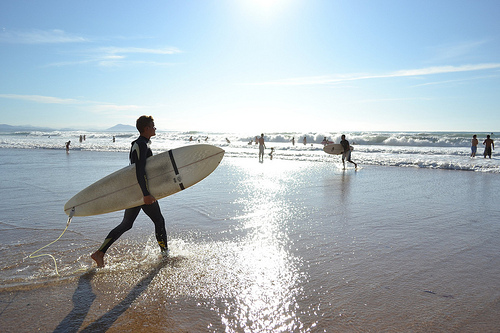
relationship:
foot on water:
[90, 252, 105, 267] [4, 132, 498, 330]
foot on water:
[162, 247, 178, 262] [4, 132, 498, 330]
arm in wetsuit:
[134, 153, 156, 207] [115, 130, 169, 267]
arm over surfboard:
[134, 153, 156, 207] [27, 145, 262, 220]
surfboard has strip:
[65, 144, 230, 231] [168, 149, 181, 192]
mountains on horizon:
[0, 117, 136, 134] [0, 104, 490, 132]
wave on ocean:
[222, 153, 498, 173] [2, 127, 498, 326]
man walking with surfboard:
[77, 117, 181, 269] [65, 144, 230, 231]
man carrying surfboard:
[77, 117, 181, 269] [65, 144, 230, 231]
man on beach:
[77, 117, 181, 269] [3, 128, 498, 331]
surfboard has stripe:
[65, 144, 230, 231] [167, 151, 184, 191]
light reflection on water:
[206, 142, 343, 331] [4, 132, 498, 330]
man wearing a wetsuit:
[77, 117, 181, 269] [97, 133, 174, 256]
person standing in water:
[483, 135, 495, 158] [4, 132, 498, 330]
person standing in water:
[469, 132, 481, 155] [4, 132, 498, 330]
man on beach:
[254, 127, 266, 160] [402, 159, 496, 244]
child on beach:
[269, 142, 276, 158] [402, 159, 496, 244]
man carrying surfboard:
[119, 119, 176, 256] [64, 143, 229, 213]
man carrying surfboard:
[337, 133, 358, 170] [321, 141, 354, 156]